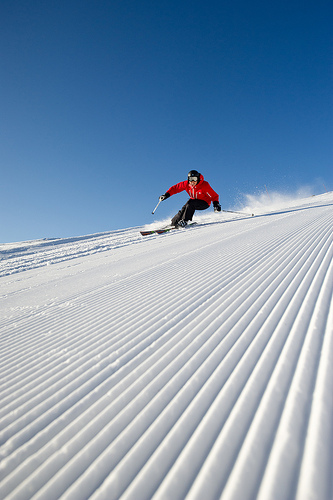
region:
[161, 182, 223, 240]
this is a skier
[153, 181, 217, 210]
this is a jacket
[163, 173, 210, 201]
this is a helmet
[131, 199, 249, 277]
this is a pair of pants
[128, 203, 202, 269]
the pants are black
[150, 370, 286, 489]
these are deep lines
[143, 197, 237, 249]
this is a pole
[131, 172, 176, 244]
the pole is metal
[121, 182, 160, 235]
these are two poles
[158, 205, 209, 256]
this is a pair of shoes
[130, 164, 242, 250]
skier going down hill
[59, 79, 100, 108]
white clouds in blue sky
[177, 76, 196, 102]
white clouds in blue sky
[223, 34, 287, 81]
white clouds in blue sky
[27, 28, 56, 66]
white clouds in blue sky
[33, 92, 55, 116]
white clouds in blue sky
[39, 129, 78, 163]
white clouds in blue sky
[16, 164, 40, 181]
white clouds in blue sky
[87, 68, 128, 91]
white clouds in blue sky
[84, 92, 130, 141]
white clouds in blue sky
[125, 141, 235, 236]
this is a person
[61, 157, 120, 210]
the sky has no clouds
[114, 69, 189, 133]
the sky has no clouds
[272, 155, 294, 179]
the sky has no clouds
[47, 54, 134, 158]
the sky has no clouds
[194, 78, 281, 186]
the sky has no clouds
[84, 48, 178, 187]
the sky has no clouds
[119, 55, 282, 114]
the sky has no clouds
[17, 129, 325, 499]
skier coming down a slope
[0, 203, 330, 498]
snow over a hill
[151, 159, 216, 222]
skier wears a red coat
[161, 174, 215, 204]
red coat has a hood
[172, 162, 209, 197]
skier has a black helmet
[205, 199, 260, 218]
snow pole on left hand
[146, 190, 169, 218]
snow pole on right hand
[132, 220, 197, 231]
a pair of skies on the snow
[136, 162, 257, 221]
skier holds snow poles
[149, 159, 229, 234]
pants of skier are black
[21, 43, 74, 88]
white clouds in blue sky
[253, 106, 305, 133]
white clouds in blue sky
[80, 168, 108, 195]
white clouds in blue sky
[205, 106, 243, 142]
white clouds in blue sky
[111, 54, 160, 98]
white clouds in blue sky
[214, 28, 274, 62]
white clouds in blue sky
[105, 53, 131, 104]
white clouds in blue sky